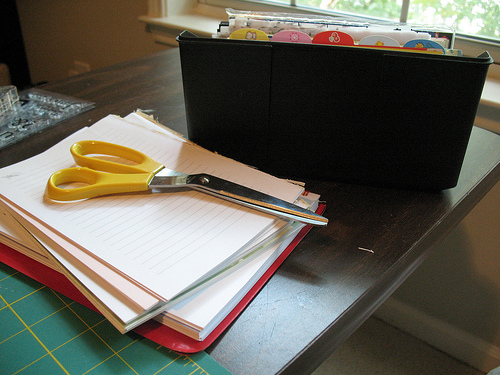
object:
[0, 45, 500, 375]
table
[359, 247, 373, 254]
white line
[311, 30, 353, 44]
tab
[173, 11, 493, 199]
folder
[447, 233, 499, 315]
ground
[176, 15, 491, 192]
box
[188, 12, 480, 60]
dividers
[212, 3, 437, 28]
craft ideas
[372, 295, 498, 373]
trim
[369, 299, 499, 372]
bottom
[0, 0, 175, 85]
wall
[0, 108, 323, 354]
book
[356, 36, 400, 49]
tab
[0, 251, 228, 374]
graph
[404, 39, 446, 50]
tab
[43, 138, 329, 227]
scissor blades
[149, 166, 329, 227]
metal blade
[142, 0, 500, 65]
window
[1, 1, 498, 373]
room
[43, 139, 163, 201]
handle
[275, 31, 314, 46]
tab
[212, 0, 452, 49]
papers